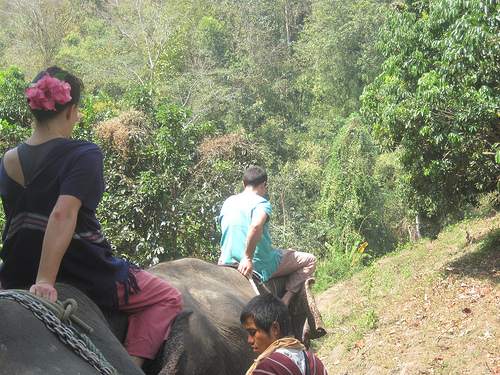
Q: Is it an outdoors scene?
A: Yes, it is outdoors.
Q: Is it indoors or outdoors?
A: It is outdoors.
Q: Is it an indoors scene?
A: No, it is outdoors.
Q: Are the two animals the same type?
A: Yes, all the animals are elephants.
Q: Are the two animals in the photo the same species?
A: Yes, all the animals are elephants.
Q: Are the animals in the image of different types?
A: No, all the animals are elephants.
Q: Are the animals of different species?
A: No, all the animals are elephants.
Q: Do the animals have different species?
A: No, all the animals are elephants.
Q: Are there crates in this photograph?
A: No, there are no crates.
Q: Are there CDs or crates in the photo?
A: No, there are no crates or cds.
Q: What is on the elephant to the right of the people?
A: The chains are on the elephant.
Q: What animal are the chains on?
A: The chains are on the elephant.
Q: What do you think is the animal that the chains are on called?
A: The animal is an elephant.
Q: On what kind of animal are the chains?
A: The chains are on the elephant.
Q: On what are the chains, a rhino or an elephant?
A: The chains are on an elephant.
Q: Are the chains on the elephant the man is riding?
A: Yes, the chains are on the elephant.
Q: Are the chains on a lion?
A: No, the chains are on the elephant.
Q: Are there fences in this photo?
A: No, there are no fences.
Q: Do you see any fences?
A: No, there are no fences.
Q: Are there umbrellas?
A: No, there are no umbrellas.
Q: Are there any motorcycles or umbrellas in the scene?
A: No, there are no umbrellas or motorcycles.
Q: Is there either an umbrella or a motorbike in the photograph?
A: No, there are no umbrellas or motorcycles.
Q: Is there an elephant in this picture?
A: Yes, there is an elephant.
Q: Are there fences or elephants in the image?
A: Yes, there is an elephant.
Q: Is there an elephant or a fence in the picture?
A: Yes, there is an elephant.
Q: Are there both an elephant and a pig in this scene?
A: No, there is an elephant but no pigs.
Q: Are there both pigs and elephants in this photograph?
A: No, there is an elephant but no pigs.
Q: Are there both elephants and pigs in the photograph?
A: No, there is an elephant but no pigs.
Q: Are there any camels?
A: No, there are no camels.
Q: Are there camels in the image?
A: No, there are no camels.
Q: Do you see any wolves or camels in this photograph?
A: No, there are no camels or wolves.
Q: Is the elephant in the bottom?
A: Yes, the elephant is in the bottom of the image.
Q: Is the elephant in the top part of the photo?
A: No, the elephant is in the bottom of the image.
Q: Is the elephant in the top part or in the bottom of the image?
A: The elephant is in the bottom of the image.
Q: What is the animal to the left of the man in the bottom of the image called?
A: The animal is an elephant.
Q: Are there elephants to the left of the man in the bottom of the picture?
A: Yes, there is an elephant to the left of the man.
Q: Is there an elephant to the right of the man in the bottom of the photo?
A: No, the elephant is to the left of the man.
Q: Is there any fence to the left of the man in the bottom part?
A: No, there is an elephant to the left of the man.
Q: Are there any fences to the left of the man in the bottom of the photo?
A: No, there is an elephant to the left of the man.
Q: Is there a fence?
A: No, there are no fences.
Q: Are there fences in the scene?
A: No, there are no fences.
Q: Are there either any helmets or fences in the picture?
A: No, there are no fences or helmets.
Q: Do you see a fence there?
A: No, there are no fences.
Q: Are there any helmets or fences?
A: No, there are no fences or helmets.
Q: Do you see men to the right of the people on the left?
A: Yes, there is a man to the right of the people.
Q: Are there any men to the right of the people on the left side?
A: Yes, there is a man to the right of the people.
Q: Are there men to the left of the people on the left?
A: No, the man is to the right of the people.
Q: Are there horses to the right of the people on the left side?
A: No, there is a man to the right of the people.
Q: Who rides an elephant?
A: The man rides an elephant.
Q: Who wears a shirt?
A: The man wears a shirt.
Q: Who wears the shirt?
A: The man wears a shirt.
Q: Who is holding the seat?
A: The man is holding the seat.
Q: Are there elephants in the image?
A: Yes, there is an elephant.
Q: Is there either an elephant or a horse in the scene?
A: Yes, there is an elephant.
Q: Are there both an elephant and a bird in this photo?
A: No, there is an elephant but no birds.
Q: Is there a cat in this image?
A: No, there are no cats.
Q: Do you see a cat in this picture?
A: No, there are no cats.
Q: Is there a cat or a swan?
A: No, there are no cats or swans.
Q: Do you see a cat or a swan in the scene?
A: No, there are no cats or swans.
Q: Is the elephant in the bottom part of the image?
A: Yes, the elephant is in the bottom of the image.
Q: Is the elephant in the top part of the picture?
A: No, the elephant is in the bottom of the image.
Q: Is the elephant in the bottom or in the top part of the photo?
A: The elephant is in the bottom of the image.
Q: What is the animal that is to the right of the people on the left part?
A: The animal is an elephant.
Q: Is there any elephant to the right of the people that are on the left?
A: Yes, there is an elephant to the right of the people.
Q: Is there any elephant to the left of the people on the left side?
A: No, the elephant is to the right of the people.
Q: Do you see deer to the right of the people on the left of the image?
A: No, there is an elephant to the right of the people.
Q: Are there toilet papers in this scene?
A: No, there are no toilet papers.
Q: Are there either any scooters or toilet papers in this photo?
A: No, there are no toilet papers or scooters.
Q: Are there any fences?
A: No, there are no fences.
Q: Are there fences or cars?
A: No, there are no fences or cars.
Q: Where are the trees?
A: The trees are on the hill.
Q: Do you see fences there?
A: No, there are no fences.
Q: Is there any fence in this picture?
A: No, there are no fences.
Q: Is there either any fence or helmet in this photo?
A: No, there are no fences or helmets.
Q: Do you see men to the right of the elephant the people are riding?
A: Yes, there is a man to the right of the elephant.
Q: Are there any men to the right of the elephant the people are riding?
A: Yes, there is a man to the right of the elephant.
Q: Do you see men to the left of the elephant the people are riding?
A: No, the man is to the right of the elephant.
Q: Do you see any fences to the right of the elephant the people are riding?
A: No, there is a man to the right of the elephant.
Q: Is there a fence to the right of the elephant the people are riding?
A: No, there is a man to the right of the elephant.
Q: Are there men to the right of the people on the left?
A: Yes, there is a man to the right of the people.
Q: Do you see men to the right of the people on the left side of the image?
A: Yes, there is a man to the right of the people.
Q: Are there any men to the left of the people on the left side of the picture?
A: No, the man is to the right of the people.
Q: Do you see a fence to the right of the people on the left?
A: No, there is a man to the right of the people.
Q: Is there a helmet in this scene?
A: No, there are no helmets.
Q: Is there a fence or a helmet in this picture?
A: No, there are no helmets or fences.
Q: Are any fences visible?
A: No, there are no fences.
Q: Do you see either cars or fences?
A: No, there are no fences or cars.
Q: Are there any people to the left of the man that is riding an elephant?
A: Yes, there are people to the left of the man.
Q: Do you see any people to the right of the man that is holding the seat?
A: No, the people are to the left of the man.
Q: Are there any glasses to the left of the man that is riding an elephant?
A: No, there are people to the left of the man.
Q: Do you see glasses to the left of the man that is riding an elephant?
A: No, there are people to the left of the man.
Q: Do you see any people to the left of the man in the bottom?
A: Yes, there are people to the left of the man.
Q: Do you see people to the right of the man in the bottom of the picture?
A: No, the people are to the left of the man.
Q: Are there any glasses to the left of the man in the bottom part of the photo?
A: No, there are people to the left of the man.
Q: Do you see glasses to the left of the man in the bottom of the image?
A: No, there are people to the left of the man.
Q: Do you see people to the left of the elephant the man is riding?
A: Yes, there are people to the left of the elephant.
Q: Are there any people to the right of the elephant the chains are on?
A: No, the people are to the left of the elephant.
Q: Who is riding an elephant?
A: The people are riding an elephant.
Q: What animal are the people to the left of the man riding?
A: The people are riding an elephant.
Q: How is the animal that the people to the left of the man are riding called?
A: The animal is an elephant.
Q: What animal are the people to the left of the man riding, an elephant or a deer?
A: The people are riding an elephant.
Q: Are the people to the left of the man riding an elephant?
A: Yes, the people are riding an elephant.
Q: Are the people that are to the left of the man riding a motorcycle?
A: No, the people are riding an elephant.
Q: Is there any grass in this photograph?
A: Yes, there is grass.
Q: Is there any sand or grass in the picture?
A: Yes, there is grass.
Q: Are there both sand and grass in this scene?
A: No, there is grass but no sand.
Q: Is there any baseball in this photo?
A: No, there are no baseballs.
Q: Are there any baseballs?
A: No, there are no baseballs.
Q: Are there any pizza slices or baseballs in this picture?
A: No, there are no baseballs or pizza slices.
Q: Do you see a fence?
A: No, there are no fences.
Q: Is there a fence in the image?
A: No, there are no fences.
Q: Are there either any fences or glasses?
A: No, there are no fences or glasses.